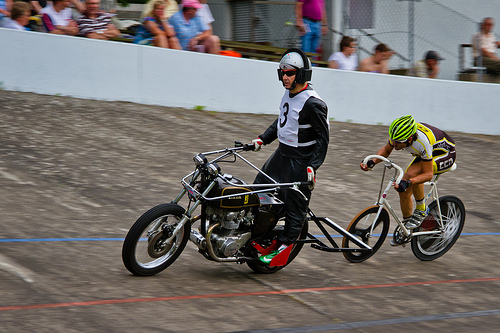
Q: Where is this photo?
A: On a track.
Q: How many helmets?
A: Two.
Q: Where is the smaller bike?
A: In back.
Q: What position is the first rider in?
A: Standing.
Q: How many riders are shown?
A: Two.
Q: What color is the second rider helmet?
A: Green.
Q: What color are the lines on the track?
A: Blue and red.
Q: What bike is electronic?
A: The one in front.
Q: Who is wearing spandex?
A: The second rider.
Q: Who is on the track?
A: The riders.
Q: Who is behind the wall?
A: Spectators.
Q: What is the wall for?
A: Separating track from stands.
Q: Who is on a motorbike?
A: A man.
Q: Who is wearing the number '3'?
A: The man on the motorcycle.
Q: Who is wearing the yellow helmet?
A: Cyclist.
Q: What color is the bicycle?
A: White.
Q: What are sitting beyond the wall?
A: Spectators.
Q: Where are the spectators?
A: In the stands.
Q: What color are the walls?
A: White.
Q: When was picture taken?
A: During daylight hours.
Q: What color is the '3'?
A: Black.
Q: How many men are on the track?
A: Two.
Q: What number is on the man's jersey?
A: 3.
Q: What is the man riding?
A: A motorcycle.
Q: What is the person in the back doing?
A: Riding a bicycle.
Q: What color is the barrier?
A: White.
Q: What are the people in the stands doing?
A: Watching the bike riders.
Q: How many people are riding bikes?
A: Two.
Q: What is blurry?
A: The people in the background.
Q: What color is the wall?
A: White.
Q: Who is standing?
A: The man on the first bike.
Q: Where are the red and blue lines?
A: On the ground.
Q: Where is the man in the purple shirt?
A: In the stands.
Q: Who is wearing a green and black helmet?
A: The second bike rider.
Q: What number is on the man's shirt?
A: Three.